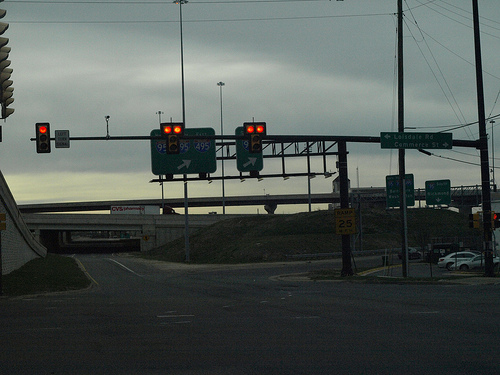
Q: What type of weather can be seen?
A: Cloudy.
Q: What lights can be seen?
A: Stop lights.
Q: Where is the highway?
A: Above the road.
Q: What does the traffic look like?
A: No traffic.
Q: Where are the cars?
A: Parked in the lot.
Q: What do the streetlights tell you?
A: To stop.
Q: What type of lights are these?
A: Traffic lights.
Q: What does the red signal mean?
A: Stop.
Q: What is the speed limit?
A: 25 mph.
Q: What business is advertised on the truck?
A: CVS Pharmacy.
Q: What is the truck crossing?
A: Bridge.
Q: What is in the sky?
A: Clouds.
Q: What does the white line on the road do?
A: Divides lanes.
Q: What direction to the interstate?
A: Right.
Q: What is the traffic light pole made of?
A: Metal.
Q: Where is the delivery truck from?
A: CVS Pharmacies.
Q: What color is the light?
A: Red.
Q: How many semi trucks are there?
A: 1.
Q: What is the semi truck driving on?
A: A bridge.